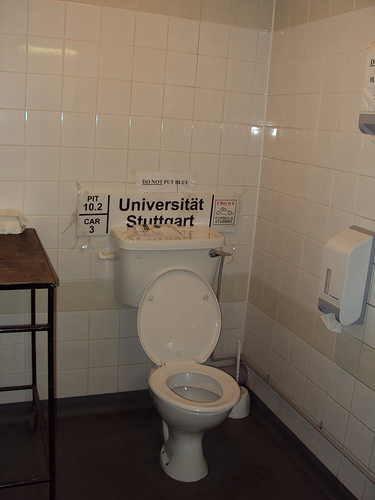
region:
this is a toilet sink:
[136, 324, 244, 419]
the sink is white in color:
[174, 394, 193, 433]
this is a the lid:
[152, 276, 208, 360]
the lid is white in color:
[155, 293, 197, 338]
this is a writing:
[123, 193, 206, 224]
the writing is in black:
[122, 195, 199, 223]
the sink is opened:
[164, 361, 232, 416]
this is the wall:
[70, 296, 132, 405]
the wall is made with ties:
[69, 320, 115, 350]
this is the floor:
[69, 437, 151, 484]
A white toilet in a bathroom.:
[108, 225, 243, 482]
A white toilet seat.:
[146, 360, 242, 416]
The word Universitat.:
[116, 196, 206, 212]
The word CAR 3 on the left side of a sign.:
[83, 217, 102, 233]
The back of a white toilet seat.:
[134, 268, 222, 366]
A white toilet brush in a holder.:
[227, 340, 249, 420]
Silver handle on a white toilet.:
[207, 246, 232, 260]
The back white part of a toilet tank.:
[111, 223, 226, 311]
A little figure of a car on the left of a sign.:
[212, 203, 233, 216]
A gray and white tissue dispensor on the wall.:
[316, 222, 374, 328]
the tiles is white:
[73, 45, 187, 135]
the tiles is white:
[99, 88, 152, 115]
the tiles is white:
[64, 21, 115, 87]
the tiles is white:
[109, 54, 152, 122]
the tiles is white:
[116, 77, 147, 110]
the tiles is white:
[107, 80, 222, 216]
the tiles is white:
[116, 81, 186, 154]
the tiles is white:
[124, 92, 218, 168]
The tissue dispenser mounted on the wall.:
[312, 222, 369, 332]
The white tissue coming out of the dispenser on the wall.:
[321, 311, 340, 337]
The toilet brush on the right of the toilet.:
[234, 329, 265, 419]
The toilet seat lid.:
[147, 265, 222, 352]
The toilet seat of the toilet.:
[160, 349, 236, 413]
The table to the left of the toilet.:
[3, 225, 66, 497]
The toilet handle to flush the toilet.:
[202, 245, 235, 261]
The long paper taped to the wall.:
[73, 188, 244, 240]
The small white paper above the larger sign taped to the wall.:
[138, 171, 198, 190]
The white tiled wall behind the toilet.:
[3, 1, 258, 395]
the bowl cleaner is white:
[215, 326, 268, 427]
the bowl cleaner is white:
[235, 264, 273, 489]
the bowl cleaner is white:
[220, 338, 258, 476]